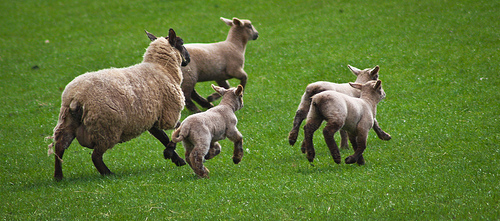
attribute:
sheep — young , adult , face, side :
[42, 12, 389, 185]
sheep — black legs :
[42, 138, 120, 188]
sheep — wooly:
[48, 19, 197, 183]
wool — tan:
[52, 40, 190, 152]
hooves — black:
[302, 139, 365, 167]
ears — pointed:
[219, 9, 243, 30]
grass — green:
[4, 0, 496, 218]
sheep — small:
[159, 73, 248, 176]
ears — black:
[139, 22, 184, 48]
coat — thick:
[60, 44, 190, 146]